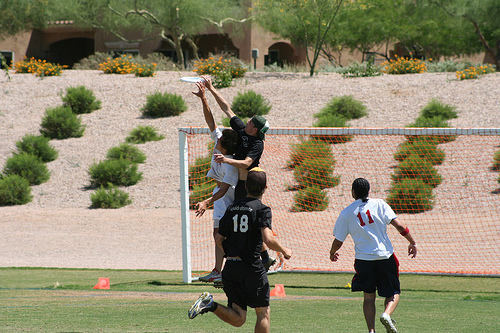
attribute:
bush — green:
[140, 94, 188, 116]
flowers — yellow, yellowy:
[116, 57, 130, 69]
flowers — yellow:
[24, 57, 59, 74]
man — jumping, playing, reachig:
[232, 111, 270, 157]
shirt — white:
[343, 200, 398, 258]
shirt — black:
[220, 200, 275, 251]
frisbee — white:
[182, 71, 200, 86]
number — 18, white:
[231, 212, 254, 240]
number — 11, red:
[354, 207, 379, 231]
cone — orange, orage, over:
[87, 278, 120, 292]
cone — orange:
[265, 281, 288, 298]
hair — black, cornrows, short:
[354, 177, 370, 191]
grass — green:
[77, 299, 100, 318]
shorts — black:
[223, 260, 266, 303]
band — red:
[397, 222, 410, 240]